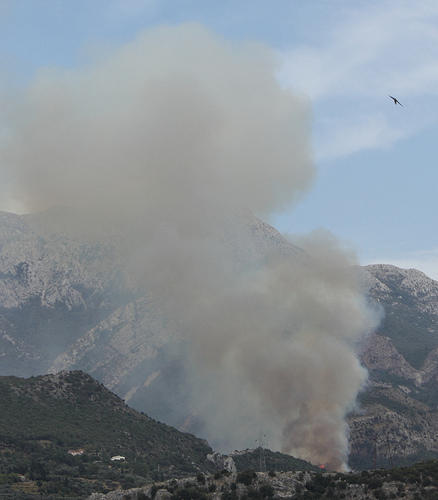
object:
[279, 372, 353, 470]
ash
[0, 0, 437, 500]
daytime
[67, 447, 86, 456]
building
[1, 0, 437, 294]
sky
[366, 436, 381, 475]
power pole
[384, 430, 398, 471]
power pole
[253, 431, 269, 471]
electricaltower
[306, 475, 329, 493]
bush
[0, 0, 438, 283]
cloud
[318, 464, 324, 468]
flame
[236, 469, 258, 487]
tree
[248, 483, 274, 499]
tree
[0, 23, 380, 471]
smoke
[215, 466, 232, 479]
tree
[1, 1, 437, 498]
outdoors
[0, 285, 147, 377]
patch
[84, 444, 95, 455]
plants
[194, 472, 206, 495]
trees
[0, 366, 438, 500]
mountain top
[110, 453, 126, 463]
rock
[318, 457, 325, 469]
fire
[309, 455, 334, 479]
lava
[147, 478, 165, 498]
spot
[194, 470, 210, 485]
spot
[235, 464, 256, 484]
spot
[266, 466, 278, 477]
spot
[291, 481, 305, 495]
spot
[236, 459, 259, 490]
tree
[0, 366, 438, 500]
mountain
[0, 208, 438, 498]
hill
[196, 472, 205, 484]
tree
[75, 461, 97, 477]
tree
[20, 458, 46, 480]
tree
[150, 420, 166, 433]
tree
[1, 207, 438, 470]
mountain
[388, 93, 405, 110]
bird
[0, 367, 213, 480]
hillside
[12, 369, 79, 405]
dirt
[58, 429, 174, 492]
ground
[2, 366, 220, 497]
vegetation